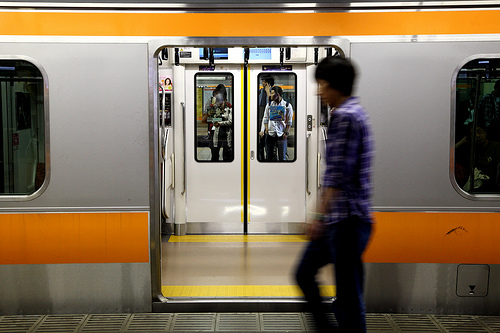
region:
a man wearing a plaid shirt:
[295, 48, 382, 322]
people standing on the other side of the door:
[203, 80, 290, 155]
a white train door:
[176, 77, 306, 234]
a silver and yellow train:
[9, 6, 493, 295]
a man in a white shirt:
[267, 90, 287, 151]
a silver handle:
[177, 103, 187, 198]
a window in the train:
[450, 50, 498, 197]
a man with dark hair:
[313, 58, 365, 113]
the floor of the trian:
[163, 235, 318, 295]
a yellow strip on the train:
[4, 9, 498, 34]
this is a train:
[1, 48, 486, 311]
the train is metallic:
[81, 159, 156, 207]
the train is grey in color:
[75, 164, 118, 197]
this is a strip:
[69, 216, 132, 261]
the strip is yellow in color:
[88, 223, 149, 253]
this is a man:
[291, 58, 388, 330]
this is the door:
[173, 59, 303, 235]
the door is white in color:
[201, 198, 226, 213]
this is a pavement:
[211, 314, 241, 331]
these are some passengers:
[209, 73, 289, 148]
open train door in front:
[153, 45, 343, 305]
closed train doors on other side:
[179, 50, 320, 236]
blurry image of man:
[288, 52, 380, 330]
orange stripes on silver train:
[1, 3, 498, 263]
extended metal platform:
[0, 310, 499, 331]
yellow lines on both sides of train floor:
[162, 228, 337, 298]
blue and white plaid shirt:
[315, 93, 379, 230]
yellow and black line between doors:
[237, 66, 252, 233]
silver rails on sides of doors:
[175, 98, 320, 201]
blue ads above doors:
[183, 47, 277, 66]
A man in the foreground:
[278, 46, 396, 330]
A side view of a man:
[283, 51, 393, 331]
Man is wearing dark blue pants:
[274, 219, 396, 330]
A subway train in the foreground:
[1, 8, 498, 320]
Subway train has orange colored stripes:
[3, 3, 498, 278]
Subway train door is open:
[139, 39, 360, 315]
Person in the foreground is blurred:
[276, 51, 398, 331]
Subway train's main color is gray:
[1, 3, 498, 322]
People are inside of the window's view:
[194, 74, 296, 164]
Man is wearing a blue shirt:
[293, 89, 399, 244]